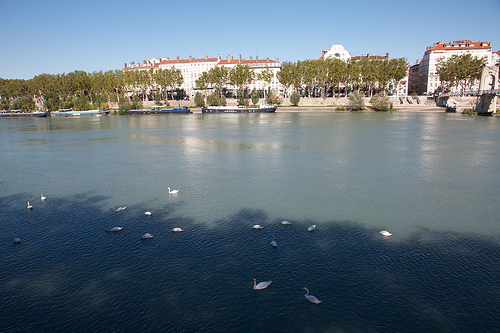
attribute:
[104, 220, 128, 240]
swan — white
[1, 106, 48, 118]
boat —  long ,  blue ,  white 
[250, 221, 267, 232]
bird — white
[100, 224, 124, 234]
bird — white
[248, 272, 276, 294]
swan — white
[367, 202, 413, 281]
canel — blue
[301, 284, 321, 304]
bird — white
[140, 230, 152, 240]
bird — white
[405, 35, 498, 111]
building — city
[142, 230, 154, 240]
swan — white 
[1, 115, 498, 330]
canal — blue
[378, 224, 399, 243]
bird — white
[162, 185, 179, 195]
bird — white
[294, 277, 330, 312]
bird/water — white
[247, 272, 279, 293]
bird/water — white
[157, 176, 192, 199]
bird/water — white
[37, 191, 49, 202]
bird — white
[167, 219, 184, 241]
swan — white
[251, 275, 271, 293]
swan — white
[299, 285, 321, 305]
swan — white 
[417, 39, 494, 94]
building — white 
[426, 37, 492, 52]
roof — red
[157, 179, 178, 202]
swan — white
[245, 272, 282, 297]
swan — white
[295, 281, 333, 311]
swan — white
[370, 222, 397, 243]
swan — white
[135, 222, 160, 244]
swan — white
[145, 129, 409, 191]
canal — blue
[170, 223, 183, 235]
bird — white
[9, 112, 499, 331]
water — white, blue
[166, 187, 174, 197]
neck — long 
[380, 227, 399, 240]
swan — white